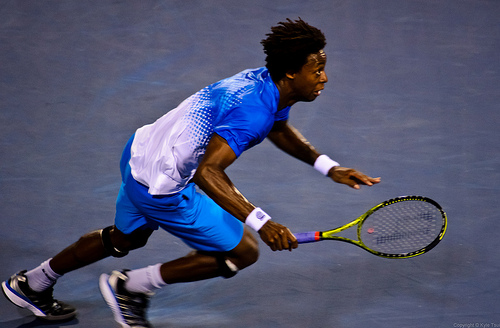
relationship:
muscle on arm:
[196, 176, 249, 222] [192, 104, 270, 234]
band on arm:
[313, 154, 340, 176] [196, 165, 296, 251]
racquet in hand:
[289, 195, 448, 256] [247, 201, 307, 263]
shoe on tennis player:
[1, 269, 77, 321] [4, 18, 377, 326]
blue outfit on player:
[127, 66, 290, 192] [3, 19, 383, 325]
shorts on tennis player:
[112, 134, 241, 253] [4, 18, 377, 326]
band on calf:
[99, 225, 126, 256] [35, 188, 132, 265]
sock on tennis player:
[25, 260, 58, 292] [4, 18, 377, 326]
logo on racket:
[371, 212, 433, 249] [288, 190, 451, 260]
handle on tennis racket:
[290, 230, 316, 244] [291, 192, 448, 258]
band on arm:
[245, 207, 272, 232] [193, 125, 302, 251]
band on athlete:
[313, 154, 340, 176] [0, 15, 382, 325]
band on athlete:
[245, 207, 272, 232] [0, 15, 382, 325]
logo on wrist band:
[256, 210, 266, 225] [243, 199, 277, 240]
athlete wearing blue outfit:
[0, 15, 382, 325] [113, 64, 278, 260]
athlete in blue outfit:
[0, 15, 382, 325] [127, 66, 290, 192]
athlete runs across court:
[0, 15, 382, 325] [0, 0, 498, 327]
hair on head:
[247, 17, 327, 58] [275, 28, 328, 105]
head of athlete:
[275, 28, 328, 105] [0, 15, 382, 325]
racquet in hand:
[244, 162, 499, 297] [257, 220, 297, 251]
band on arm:
[245, 207, 272, 232] [192, 104, 273, 220]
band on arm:
[313, 154, 340, 176] [267, 107, 320, 165]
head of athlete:
[259, 17, 329, 102] [0, 15, 382, 325]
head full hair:
[259, 17, 329, 102] [261, 14, 326, 84]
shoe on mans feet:
[1, 269, 81, 326] [2, 267, 156, 327]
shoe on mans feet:
[97, 267, 156, 327] [2, 267, 156, 327]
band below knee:
[198, 254, 242, 286] [204, 227, 266, 272]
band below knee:
[94, 219, 135, 264] [111, 216, 158, 257]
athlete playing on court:
[51, 26, 483, 326] [0, 0, 498, 327]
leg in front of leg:
[99, 199, 258, 321] [3, 184, 140, 321]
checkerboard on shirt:
[148, 72, 284, 164] [128, 65, 289, 195]